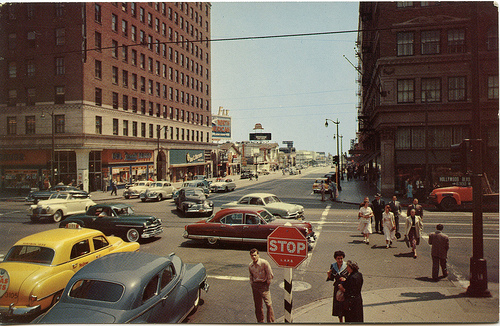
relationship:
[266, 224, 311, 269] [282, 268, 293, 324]
stop sign on top of pole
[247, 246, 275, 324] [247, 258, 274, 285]
man wearing shirt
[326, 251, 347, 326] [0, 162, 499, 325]
woman talking on street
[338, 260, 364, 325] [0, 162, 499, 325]
woman talking on street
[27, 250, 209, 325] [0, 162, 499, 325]
car on street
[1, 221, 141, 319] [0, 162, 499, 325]
taxi cab on street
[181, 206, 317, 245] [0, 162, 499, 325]
car on street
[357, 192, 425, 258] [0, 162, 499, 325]
group crossing street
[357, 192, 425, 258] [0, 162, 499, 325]
group are crossing street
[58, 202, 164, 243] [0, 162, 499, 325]
car on street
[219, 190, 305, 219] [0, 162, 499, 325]
car on street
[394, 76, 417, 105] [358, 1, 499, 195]
window in building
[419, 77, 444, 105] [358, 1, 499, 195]
window in building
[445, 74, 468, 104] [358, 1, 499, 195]
window in building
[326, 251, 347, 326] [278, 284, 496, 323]
woman talking on sidewalk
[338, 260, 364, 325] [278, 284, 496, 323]
woman talking on sidewalk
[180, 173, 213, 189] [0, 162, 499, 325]
car driving in road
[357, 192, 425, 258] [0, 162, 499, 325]
people are crossing street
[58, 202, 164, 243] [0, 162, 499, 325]
car on road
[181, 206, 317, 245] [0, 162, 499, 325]
car on road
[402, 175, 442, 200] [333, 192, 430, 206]
people are along sidewalk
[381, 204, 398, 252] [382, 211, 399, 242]
woman wearing dress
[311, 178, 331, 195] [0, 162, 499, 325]
vehicle on street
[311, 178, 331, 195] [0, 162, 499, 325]
vehicle parked on street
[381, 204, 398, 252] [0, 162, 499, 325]
woman walking across street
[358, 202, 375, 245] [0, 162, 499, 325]
woman walking across street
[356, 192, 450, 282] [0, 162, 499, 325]
people are walking across street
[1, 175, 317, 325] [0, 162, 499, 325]
vehicles are in street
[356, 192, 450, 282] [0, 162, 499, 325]
people are crossing street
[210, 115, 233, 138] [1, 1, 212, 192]
billboard behind building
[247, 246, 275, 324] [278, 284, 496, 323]
man standing on corner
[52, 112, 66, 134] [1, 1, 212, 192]
window on building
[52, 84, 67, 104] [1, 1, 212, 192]
window on building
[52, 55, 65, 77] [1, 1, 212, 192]
window on building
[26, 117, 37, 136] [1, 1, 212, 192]
window on building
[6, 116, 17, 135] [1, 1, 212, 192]
window on building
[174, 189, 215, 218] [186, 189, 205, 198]
vehicle has window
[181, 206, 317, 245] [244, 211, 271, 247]
vehicle has door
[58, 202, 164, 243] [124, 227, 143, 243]
vehicle has tire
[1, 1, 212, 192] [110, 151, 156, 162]
building has lettering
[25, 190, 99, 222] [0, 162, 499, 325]
car on street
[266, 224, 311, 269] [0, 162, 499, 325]
sign on street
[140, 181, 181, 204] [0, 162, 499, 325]
car on street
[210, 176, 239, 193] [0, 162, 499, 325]
car on street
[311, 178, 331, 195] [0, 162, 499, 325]
taxi on street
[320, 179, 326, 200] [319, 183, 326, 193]
man wearing shirt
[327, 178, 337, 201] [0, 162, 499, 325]
man standing on street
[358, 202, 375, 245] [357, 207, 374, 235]
woman wearing dress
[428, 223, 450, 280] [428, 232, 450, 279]
man wearing suit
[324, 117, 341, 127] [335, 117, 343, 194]
light on top of pole